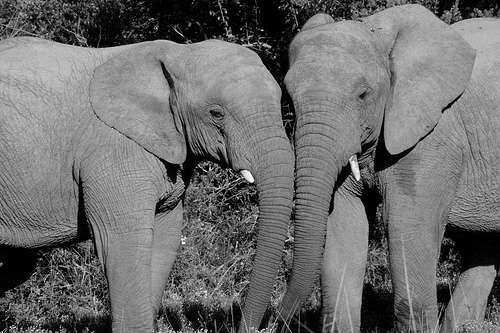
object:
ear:
[86, 50, 189, 165]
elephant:
[0, 33, 296, 332]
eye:
[208, 108, 226, 120]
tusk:
[238, 168, 257, 184]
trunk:
[234, 90, 297, 332]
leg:
[77, 150, 164, 333]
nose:
[274, 95, 363, 324]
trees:
[11, 2, 139, 49]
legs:
[148, 199, 186, 322]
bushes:
[169, 220, 235, 324]